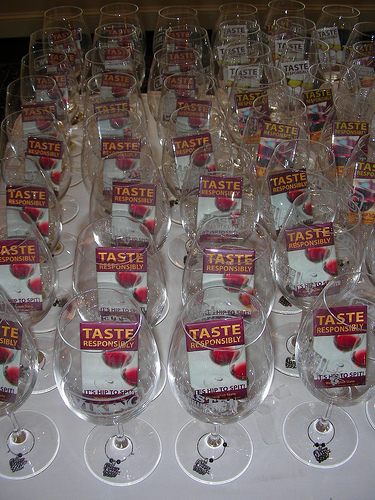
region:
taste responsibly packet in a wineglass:
[180, 315, 252, 410]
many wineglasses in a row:
[35, 113, 345, 471]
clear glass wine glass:
[163, 291, 272, 489]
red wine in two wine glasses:
[204, 332, 246, 393]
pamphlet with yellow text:
[179, 316, 250, 412]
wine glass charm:
[189, 426, 231, 486]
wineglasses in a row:
[20, 206, 371, 440]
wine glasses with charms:
[59, 288, 286, 483]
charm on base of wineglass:
[180, 425, 241, 472]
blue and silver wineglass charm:
[97, 425, 135, 486]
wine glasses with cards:
[104, 185, 372, 398]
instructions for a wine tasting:
[177, 320, 257, 431]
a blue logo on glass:
[182, 447, 227, 483]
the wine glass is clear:
[167, 424, 246, 483]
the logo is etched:
[175, 366, 261, 430]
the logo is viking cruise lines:
[53, 366, 181, 426]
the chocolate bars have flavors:
[156, 37, 325, 187]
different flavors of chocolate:
[57, 24, 353, 222]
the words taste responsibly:
[187, 318, 313, 372]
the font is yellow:
[172, 311, 242, 343]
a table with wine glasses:
[27, 34, 353, 434]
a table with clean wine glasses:
[44, 28, 324, 429]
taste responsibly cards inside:
[27, 81, 364, 449]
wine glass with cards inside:
[9, 177, 343, 458]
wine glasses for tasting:
[40, 206, 337, 469]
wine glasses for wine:
[46, 176, 366, 426]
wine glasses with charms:
[13, 212, 225, 497]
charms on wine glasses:
[30, 211, 364, 499]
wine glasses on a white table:
[24, 191, 299, 499]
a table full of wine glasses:
[32, 34, 347, 475]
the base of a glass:
[172, 411, 254, 484]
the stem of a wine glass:
[314, 397, 342, 432]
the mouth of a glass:
[175, 282, 269, 353]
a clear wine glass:
[165, 282, 271, 485]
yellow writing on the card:
[184, 320, 241, 348]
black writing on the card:
[278, 57, 308, 75]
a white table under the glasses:
[0, 79, 373, 498]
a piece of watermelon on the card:
[99, 345, 133, 370]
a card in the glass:
[76, 314, 140, 415]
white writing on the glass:
[65, 385, 145, 419]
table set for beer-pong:
[30, 136, 325, 332]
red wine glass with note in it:
[30, 306, 182, 496]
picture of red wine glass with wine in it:
[187, 320, 243, 417]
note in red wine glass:
[74, 322, 144, 401]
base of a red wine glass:
[80, 414, 159, 495]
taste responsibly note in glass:
[185, 311, 250, 353]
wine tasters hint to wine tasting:
[186, 383, 254, 402]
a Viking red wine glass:
[55, 388, 152, 428]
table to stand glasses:
[259, 438, 372, 493]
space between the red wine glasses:
[21, 428, 101, 483]